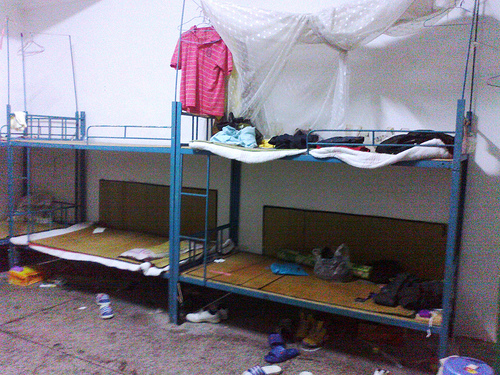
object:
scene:
[365, 343, 403, 369]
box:
[8, 265, 42, 286]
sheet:
[197, 0, 452, 141]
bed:
[173, 95, 470, 364]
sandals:
[266, 344, 298, 362]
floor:
[0, 246, 499, 374]